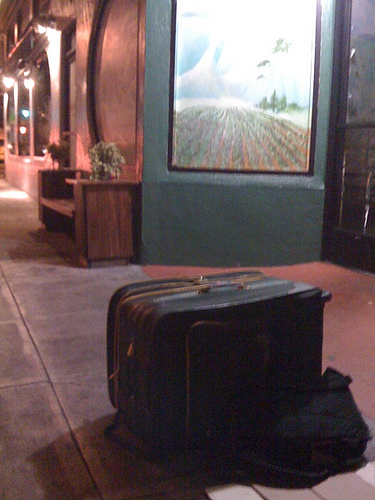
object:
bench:
[38, 169, 140, 267]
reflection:
[19, 126, 26, 134]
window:
[18, 77, 31, 153]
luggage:
[105, 269, 323, 436]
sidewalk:
[0, 173, 139, 499]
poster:
[172, 1, 315, 174]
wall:
[143, 0, 326, 266]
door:
[324, 0, 374, 260]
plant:
[88, 140, 122, 178]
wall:
[78, 0, 143, 178]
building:
[0, 0, 375, 265]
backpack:
[218, 368, 366, 485]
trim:
[107, 279, 155, 433]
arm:
[64, 178, 132, 186]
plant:
[48, 139, 68, 166]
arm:
[38, 169, 83, 173]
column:
[46, 25, 65, 170]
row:
[0, 36, 64, 159]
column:
[29, 82, 33, 154]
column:
[14, 82, 18, 155]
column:
[3, 89, 8, 154]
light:
[23, 78, 35, 90]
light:
[3, 76, 16, 89]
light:
[47, 29, 60, 44]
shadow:
[26, 406, 208, 498]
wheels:
[321, 289, 332, 301]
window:
[33, 55, 52, 156]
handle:
[196, 275, 249, 293]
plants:
[173, 106, 308, 171]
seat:
[40, 194, 75, 218]